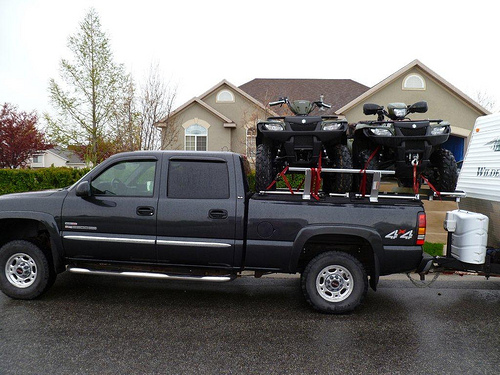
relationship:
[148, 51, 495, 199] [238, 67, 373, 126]
house has a roof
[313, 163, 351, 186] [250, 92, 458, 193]
straps on four wheelers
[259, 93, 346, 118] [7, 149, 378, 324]
handlebars on four wheeler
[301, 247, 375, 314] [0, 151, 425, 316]
tire on truck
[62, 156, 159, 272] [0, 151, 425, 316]
black door on truck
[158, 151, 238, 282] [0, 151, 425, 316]
black door on truck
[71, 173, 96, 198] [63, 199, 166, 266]
mirror on door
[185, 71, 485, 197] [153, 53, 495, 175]
walls on house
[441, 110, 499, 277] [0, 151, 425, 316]
rv attached to truck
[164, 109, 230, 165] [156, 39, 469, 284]
window on house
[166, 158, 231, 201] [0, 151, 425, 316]
window on truck